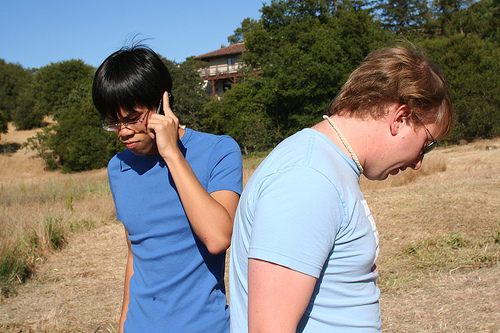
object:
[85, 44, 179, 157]
mans head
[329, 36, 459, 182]
mans head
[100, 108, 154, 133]
eyeglasses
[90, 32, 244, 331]
asian man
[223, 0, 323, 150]
trees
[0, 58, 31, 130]
trees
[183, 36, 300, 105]
house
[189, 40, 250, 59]
roof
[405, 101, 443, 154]
glasses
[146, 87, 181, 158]
hand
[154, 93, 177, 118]
cell phone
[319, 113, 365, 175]
necklace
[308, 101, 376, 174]
neck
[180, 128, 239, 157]
shoulders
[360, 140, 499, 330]
hillside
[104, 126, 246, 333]
shirt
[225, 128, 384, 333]
green shirt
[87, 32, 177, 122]
hair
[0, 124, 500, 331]
field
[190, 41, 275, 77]
floor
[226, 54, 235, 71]
door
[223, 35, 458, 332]
boy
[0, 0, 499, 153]
background